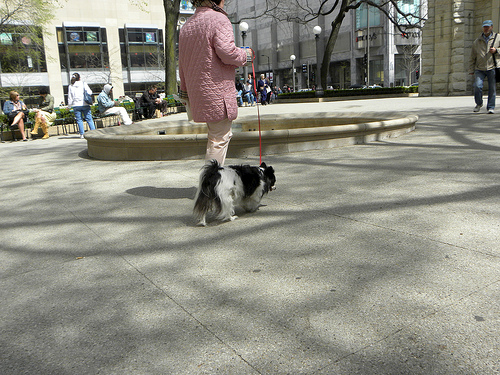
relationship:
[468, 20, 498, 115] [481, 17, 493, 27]
man wearing ball cap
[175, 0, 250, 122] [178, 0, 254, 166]
coat on person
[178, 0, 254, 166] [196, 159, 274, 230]
person walking dog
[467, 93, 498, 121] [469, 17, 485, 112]
shoes on man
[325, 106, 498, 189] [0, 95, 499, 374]
shadow on ground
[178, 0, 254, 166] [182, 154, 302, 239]
person walking dog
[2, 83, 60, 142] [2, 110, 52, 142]
women sitting on bench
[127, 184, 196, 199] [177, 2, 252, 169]
shadow of woman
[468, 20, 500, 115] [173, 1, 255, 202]
man walking towards woman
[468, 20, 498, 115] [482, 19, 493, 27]
man wearing ball cap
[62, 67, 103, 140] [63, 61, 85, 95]
woman wearing ponytail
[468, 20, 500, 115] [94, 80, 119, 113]
man wearing hoodie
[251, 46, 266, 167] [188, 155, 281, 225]
leash on dog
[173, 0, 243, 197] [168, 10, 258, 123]
person wearing jacket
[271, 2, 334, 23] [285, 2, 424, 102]
branches on tree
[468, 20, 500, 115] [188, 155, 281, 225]
man walking toward dog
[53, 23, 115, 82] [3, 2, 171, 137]
window in building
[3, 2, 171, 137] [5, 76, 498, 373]
building behind park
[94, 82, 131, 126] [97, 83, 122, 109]
person in hoodie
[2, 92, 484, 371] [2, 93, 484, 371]
sun reflected on ground